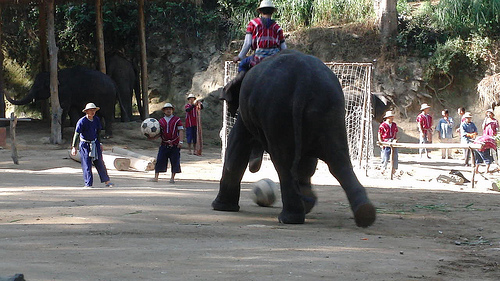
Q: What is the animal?
A: An elephant.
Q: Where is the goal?
A: In front of the elephant.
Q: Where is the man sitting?
A: On top of the elephant.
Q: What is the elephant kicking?
A: A soccer ball.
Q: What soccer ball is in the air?
A: The one on the left.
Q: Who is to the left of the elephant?
A: A man with a white hat in blue clothes.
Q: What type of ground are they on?
A: Dirt.